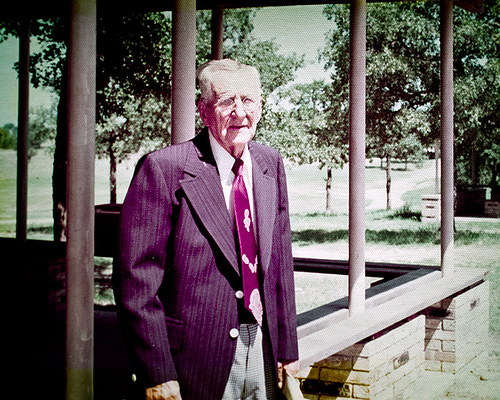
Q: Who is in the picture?
A: An old man.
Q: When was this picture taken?
A: Daytime.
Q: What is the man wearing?
A: A suit.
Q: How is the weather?
A: Sunny.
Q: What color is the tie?
A: Maroon.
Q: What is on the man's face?
A: Glasses.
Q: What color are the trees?
A: Green.